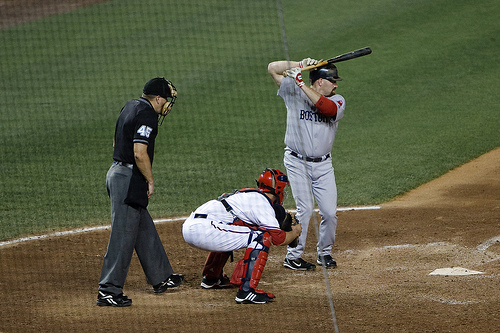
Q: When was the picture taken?
A: During a baseball game.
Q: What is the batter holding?
A: Bat.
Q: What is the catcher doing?
A: Squatting.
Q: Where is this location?
A: Baseball field.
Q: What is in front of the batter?
A: Home plate.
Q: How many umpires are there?
A: One.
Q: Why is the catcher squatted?
A: To catch pitch.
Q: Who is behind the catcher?
A: Umpire.